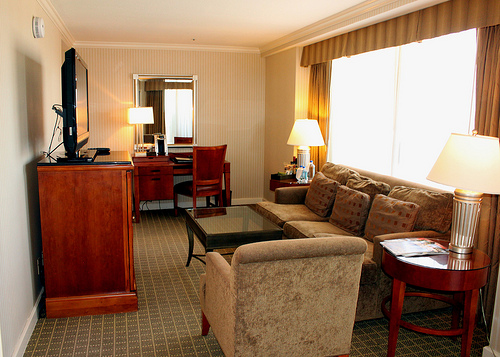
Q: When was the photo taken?
A: Daytime.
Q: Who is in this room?
A: No one.